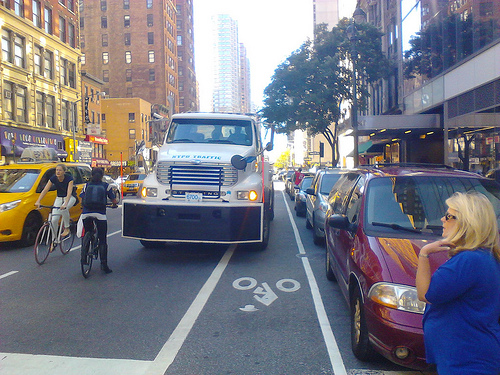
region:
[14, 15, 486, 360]
A crowded city street.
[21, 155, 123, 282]
Two people riding bicycles.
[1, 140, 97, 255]
A bright yellow vehicle.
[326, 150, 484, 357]
A red vehicle parked on the ride.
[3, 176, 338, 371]
Solid white traffic lines painted on the street.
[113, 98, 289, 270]
A large white truck coming down the street.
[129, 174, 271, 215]
The lights on the front of the truck are turned on.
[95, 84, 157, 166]
A short yellow building on the left side of the street.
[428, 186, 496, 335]
A woman with blonde hair.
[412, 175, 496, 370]
A woman wearing a blue shirt.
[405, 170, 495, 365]
A woman with blonde hair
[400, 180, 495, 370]
A woman with a pair of sunglasses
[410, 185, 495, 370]
A woman wearing a blue shirt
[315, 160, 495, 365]
A red mini van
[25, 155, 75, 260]
A woman wearing a blue shirt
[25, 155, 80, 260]
A woman riding a bike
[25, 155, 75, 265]
A woman wearing white pants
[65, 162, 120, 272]
A person riding a bike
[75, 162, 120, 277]
A person with a blue backpack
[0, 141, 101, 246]
A yellow mini van/taxi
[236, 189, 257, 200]
A headlight on a truck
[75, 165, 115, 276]
Person riding a bicycle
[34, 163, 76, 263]
Lady riding a bike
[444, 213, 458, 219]
Glasses worn by a lady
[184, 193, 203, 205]
A license plate on a truck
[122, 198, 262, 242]
A big bumper on a truck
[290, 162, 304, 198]
A person with a red shirt on waving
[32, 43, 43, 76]
A window on a building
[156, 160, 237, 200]
The grill of a big truck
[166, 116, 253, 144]
The windshield on a truck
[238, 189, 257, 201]
The car light is yellow.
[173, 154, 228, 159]
The writing on the truck is blue.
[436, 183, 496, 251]
The woman's hair is blonde.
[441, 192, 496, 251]
The woman is wearing glasses.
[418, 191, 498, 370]
The woman is wearing a blue shirt.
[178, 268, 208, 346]
There is a white stripe on the road.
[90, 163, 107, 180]
The woman's hair is brown.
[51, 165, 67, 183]
The woman's hair is blonde.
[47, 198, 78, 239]
The woman's pants are white.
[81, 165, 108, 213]
The woman is wearing a blue backpack.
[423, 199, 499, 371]
woman wearing a blue shirt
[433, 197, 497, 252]
woman wearing sunglasses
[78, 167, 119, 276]
person on a bicycle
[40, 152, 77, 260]
person on a bicycle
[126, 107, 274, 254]
white truck driving down street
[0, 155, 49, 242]
partial view of yellow taxi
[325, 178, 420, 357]
car parked on side of street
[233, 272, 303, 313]
painted picture of bicycle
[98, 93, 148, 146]
orange building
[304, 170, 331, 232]
partial view of car parked on side of street